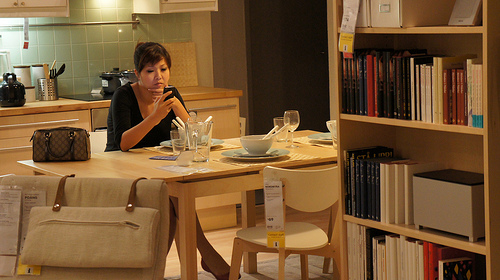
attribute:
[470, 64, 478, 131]
book — white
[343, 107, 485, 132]
shelf — tan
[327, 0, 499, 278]
bookshelf — wooden ,  for sale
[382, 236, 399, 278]
book — white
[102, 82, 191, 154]
shirt — black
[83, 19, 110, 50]
tile — green , ceramic, of backsplash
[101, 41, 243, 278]
woman — asian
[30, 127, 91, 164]
bag — gucci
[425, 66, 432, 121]
book — white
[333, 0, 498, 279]
shelf — tan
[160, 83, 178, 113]
cell phone — black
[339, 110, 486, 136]
shelf — tan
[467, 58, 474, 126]
book — white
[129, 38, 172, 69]
hair — black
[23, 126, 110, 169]
purse — grey, black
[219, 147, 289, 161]
plate — white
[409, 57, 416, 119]
book — white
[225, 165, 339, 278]
chair — wooden, for sale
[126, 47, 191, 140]
woman — Asian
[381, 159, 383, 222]
book — white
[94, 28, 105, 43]
tile — mint green, of backsplash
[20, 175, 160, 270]
bag — beige , cotton 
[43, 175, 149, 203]
handles — leather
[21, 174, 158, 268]
organizer — tan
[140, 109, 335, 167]
tableware set — for dinner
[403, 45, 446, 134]
book — white